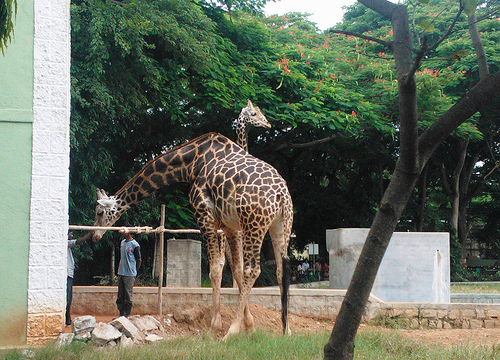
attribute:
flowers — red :
[263, 49, 320, 95]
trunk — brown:
[332, 1, 447, 333]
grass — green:
[12, 322, 499, 357]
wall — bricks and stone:
[310, 207, 492, 333]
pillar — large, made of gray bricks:
[153, 231, 209, 293]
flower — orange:
[351, 53, 366, 60]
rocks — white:
[33, 309, 229, 345]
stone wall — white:
[24, 1, 69, 334]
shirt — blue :
[105, 240, 167, 264]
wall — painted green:
[0, 0, 27, 346]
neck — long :
[80, 135, 174, 280]